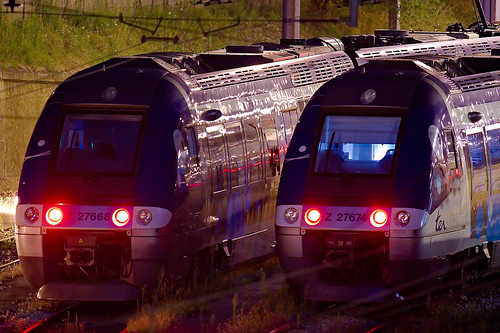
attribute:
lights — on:
[371, 143, 395, 161]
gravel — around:
[409, 290, 499, 329]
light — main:
[295, 202, 324, 234]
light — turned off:
[137, 207, 152, 226]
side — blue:
[428, 85, 497, 247]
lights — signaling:
[21, 199, 424, 241]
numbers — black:
[77, 211, 109, 221]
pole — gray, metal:
[281, 3, 306, 35]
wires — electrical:
[78, 11, 392, 46]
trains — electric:
[8, 36, 496, 321]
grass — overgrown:
[127, 263, 306, 331]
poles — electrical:
[277, 2, 414, 39]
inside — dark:
[70, 117, 122, 168]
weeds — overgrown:
[119, 266, 296, 331]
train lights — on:
[45, 203, 130, 228]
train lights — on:
[301, 204, 388, 226]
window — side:
[441, 122, 459, 159]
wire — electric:
[0, 11, 352, 48]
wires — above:
[33, 12, 413, 67]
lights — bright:
[294, 207, 391, 232]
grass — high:
[0, 0, 477, 59]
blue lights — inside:
[321, 129, 396, 173]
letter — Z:
[321, 209, 336, 228]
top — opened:
[160, 47, 277, 77]